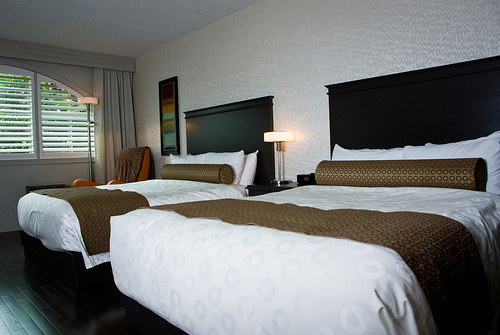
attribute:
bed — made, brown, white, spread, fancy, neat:
[262, 145, 473, 318]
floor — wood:
[24, 269, 88, 331]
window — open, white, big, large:
[7, 68, 89, 173]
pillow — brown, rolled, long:
[342, 142, 473, 165]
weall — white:
[242, 13, 340, 76]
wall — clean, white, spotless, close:
[241, 17, 322, 80]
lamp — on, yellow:
[253, 123, 306, 158]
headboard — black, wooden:
[176, 100, 280, 195]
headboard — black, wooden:
[320, 55, 499, 153]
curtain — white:
[75, 64, 149, 184]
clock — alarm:
[289, 169, 337, 199]